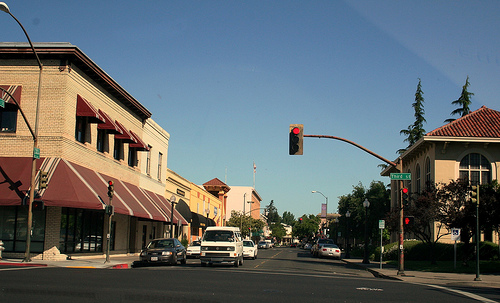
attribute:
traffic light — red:
[401, 185, 410, 210]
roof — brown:
[379, 103, 499, 178]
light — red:
[280, 129, 318, 142]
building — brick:
[41, 42, 167, 259]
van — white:
[196, 222, 243, 268]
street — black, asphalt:
[0, 242, 497, 302]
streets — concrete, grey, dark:
[1, 248, 490, 301]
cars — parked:
[103, 174, 253, 280]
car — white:
[243, 236, 259, 261]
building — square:
[227, 188, 262, 230]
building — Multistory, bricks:
[5, 50, 160, 270]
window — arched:
[447, 142, 499, 199]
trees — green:
[331, 181, 401, 260]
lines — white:
[253, 241, 334, 272]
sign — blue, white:
[442, 220, 462, 243]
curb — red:
[0, 260, 45, 272]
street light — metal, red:
[286, 121, 305, 156]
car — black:
[135, 232, 187, 267]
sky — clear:
[187, 32, 406, 147]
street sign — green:
[371, 157, 420, 286]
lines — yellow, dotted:
[253, 247, 288, 278]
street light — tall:
[309, 190, 319, 194]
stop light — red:
[288, 120, 408, 276]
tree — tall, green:
[377, 80, 428, 167]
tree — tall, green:
[446, 70, 474, 121]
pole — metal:
[397, 152, 404, 274]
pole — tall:
[396, 158, 406, 275]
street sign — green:
[387, 168, 416, 180]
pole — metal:
[394, 154, 403, 275]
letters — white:
[392, 173, 410, 180]